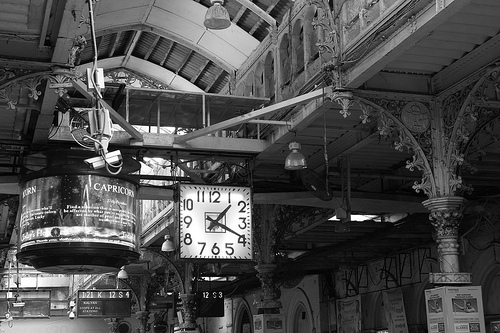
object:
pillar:
[419, 195, 475, 287]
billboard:
[71, 291, 135, 320]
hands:
[204, 201, 247, 239]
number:
[181, 198, 195, 211]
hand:
[205, 201, 235, 228]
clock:
[176, 185, 253, 262]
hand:
[206, 212, 249, 239]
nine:
[179, 216, 194, 228]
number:
[210, 235, 250, 255]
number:
[196, 242, 208, 257]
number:
[226, 191, 232, 204]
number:
[209, 190, 221, 203]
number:
[195, 188, 204, 203]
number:
[181, 232, 197, 247]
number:
[235, 217, 252, 230]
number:
[237, 200, 246, 212]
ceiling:
[4, 4, 374, 181]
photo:
[2, 1, 483, 314]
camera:
[70, 3, 127, 173]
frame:
[170, 175, 257, 195]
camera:
[81, 143, 127, 175]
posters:
[422, 283, 488, 333]